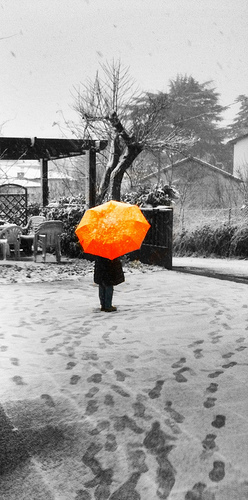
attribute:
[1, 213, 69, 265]
chairs — plastic 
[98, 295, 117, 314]
boots — brown 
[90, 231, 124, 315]
person — one, black, long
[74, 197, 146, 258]
umbrella — orange, big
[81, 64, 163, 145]
branches — some, snowy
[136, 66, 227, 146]
tree — tall, green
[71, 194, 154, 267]
umbrella — orange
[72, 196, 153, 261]
umbrella — orange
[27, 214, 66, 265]
chairs — stacked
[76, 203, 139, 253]
umbrella — orange , opened 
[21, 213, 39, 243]
chair — white 